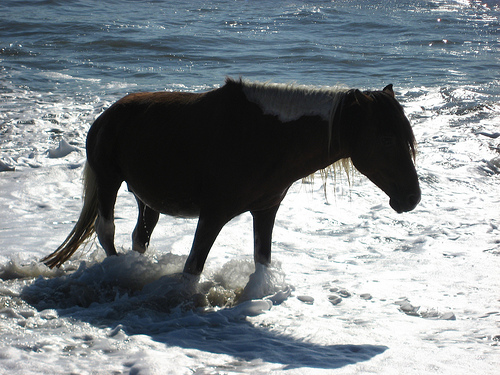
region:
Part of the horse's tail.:
[39, 242, 79, 272]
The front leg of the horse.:
[181, 217, 226, 278]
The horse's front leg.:
[251, 209, 273, 268]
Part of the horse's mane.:
[257, 83, 294, 101]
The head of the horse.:
[346, 83, 422, 213]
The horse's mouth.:
[388, 194, 420, 214]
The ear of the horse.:
[353, 86, 372, 108]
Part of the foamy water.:
[295, 314, 323, 344]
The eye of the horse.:
[378, 132, 395, 147]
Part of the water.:
[149, 27, 224, 58]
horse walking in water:
[32, 63, 435, 333]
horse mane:
[229, 71, 351, 163]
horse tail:
[33, 139, 104, 286]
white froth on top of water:
[102, 332, 207, 374]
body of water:
[3, 4, 491, 374]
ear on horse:
[372, 79, 400, 101]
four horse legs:
[87, 189, 297, 297]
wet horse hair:
[297, 154, 367, 220]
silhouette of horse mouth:
[377, 190, 429, 225]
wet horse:
[17, 21, 72, 41]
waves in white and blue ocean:
[333, 290, 394, 353]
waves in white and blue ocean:
[400, 255, 450, 325]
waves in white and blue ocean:
[33, 32, 76, 62]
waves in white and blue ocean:
[360, 7, 433, 50]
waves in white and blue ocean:
[115, 40, 145, 56]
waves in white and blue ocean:
[27, 20, 93, 76]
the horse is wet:
[51, 41, 465, 290]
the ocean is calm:
[13, 2, 498, 95]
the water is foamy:
[286, 213, 496, 370]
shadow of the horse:
[21, 263, 417, 374]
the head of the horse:
[339, 79, 452, 217]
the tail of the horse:
[33, 175, 102, 280]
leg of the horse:
[169, 199, 233, 302]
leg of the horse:
[233, 198, 285, 287]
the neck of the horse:
[266, 82, 373, 178]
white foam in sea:
[35, 64, 102, 86]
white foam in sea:
[17, 38, 26, 48]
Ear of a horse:
[349, 85, 380, 113]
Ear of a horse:
[378, 82, 399, 101]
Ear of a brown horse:
[351, 83, 375, 112]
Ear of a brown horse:
[377, 78, 399, 104]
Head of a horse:
[343, 77, 436, 220]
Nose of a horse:
[388, 181, 428, 213]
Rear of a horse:
[83, 98, 160, 195]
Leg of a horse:
[176, 227, 215, 299]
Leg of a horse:
[243, 213, 280, 290]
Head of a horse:
[345, 72, 431, 220]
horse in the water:
[45, 57, 450, 292]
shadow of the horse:
[316, 301, 406, 366]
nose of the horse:
[370, 171, 435, 231]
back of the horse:
[90, 55, 322, 155]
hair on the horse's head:
[330, 70, 407, 146]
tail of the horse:
[10, 154, 122, 302]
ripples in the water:
[79, 15, 299, 76]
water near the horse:
[105, 49, 400, 78]